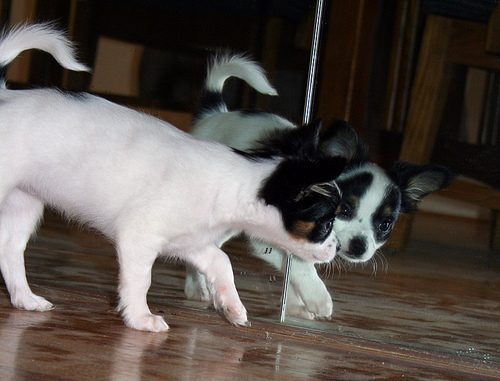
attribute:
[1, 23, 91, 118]
tail — white 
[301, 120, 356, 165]
ear — white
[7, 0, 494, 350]
mirror — large 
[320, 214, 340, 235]
eye — dark 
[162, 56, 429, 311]
puppy — black , white 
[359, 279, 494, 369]
floor — shiny , wood 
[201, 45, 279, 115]
tail — puppy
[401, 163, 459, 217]
ear — black 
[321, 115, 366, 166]
ear — black 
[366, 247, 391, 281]
whiskers — white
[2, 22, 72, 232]
end — HIND